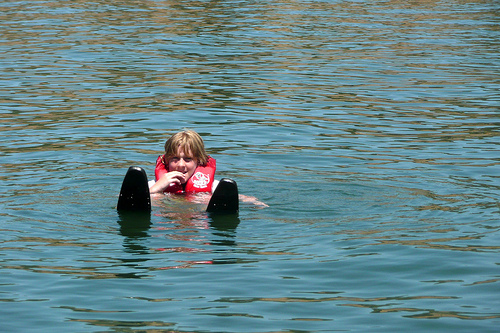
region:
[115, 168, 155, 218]
black rubber water ski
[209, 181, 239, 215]
black water skiin lake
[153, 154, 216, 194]
red and white life vest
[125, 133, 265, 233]
boy wearing life vest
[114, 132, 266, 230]
boy wearing water skis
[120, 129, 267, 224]
boy swimming in water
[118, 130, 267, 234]
boy swimming in lake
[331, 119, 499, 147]
ripple made in water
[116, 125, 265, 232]
boy playing in water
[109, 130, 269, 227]
boy floating in lake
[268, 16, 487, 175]
the water is blue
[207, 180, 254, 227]
black fins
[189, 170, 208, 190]
a life vest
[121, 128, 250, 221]
a person in the water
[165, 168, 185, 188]
the persons hand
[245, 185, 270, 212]
the persons arm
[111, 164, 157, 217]
black fin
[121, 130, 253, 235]
the person is in the water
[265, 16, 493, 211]
the water is clear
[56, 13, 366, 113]
the water is blue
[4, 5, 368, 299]
person in the water in the sun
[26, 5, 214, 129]
relatively calm water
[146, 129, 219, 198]
person in red life preserver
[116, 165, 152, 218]
black underside of water skis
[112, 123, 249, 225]
person floating in the water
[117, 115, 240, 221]
person has wet blond hair in a red water preserver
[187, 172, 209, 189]
white printed logo on life preserver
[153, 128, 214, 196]
red life preserver with white logo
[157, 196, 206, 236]
reflection of person in water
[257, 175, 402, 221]
ripple in large body of water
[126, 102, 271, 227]
boy's hair is blonde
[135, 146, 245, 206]
boy wearing a life jacket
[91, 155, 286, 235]
boy's shoes are black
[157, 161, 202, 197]
boy's hand in mouth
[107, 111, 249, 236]
boy is laying backwards in water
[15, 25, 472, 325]
small waves are in the lake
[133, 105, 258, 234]
sun shining on the boy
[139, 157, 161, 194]
boy's shirt is white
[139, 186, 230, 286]
reflection of boy in water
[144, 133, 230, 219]
bottom half of boy's body in water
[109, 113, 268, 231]
young person preparing to water ski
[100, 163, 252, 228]
tips of water skies sticking out of water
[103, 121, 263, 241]
water skiier in water with red life vest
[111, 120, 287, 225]
blonde headed young person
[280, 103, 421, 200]
water with light reflecting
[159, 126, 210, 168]
blonde hair with bangs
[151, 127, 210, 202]
person with hand near mouth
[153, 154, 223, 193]
red life vest with white logo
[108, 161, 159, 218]
tip of black water ski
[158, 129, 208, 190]
young person with shadows on face